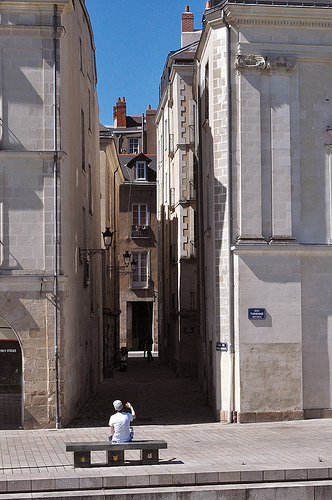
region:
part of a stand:
[150, 451, 159, 455]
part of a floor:
[229, 425, 260, 467]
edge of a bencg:
[127, 441, 140, 454]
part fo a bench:
[147, 444, 164, 471]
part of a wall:
[251, 381, 273, 420]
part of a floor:
[247, 430, 264, 457]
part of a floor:
[142, 397, 153, 407]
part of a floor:
[246, 416, 257, 433]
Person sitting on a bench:
[103, 395, 137, 468]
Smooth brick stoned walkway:
[0, 415, 331, 494]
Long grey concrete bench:
[61, 439, 173, 469]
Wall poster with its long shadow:
[245, 306, 274, 331]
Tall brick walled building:
[152, 0, 330, 428]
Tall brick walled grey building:
[0, 0, 110, 432]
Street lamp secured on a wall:
[77, 224, 116, 289]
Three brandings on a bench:
[78, 452, 156, 464]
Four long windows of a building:
[125, 126, 153, 294]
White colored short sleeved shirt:
[108, 410, 134, 445]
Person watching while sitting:
[108, 391, 143, 458]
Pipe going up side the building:
[47, 77, 65, 430]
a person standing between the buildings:
[139, 331, 158, 371]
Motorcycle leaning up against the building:
[119, 343, 130, 378]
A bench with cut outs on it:
[62, 438, 164, 466]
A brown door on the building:
[3, 331, 33, 442]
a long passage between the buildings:
[64, 331, 210, 425]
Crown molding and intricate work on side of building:
[234, 18, 326, 79]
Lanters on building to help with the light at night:
[74, 230, 119, 292]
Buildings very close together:
[99, 114, 212, 278]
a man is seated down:
[63, 381, 156, 460]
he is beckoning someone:
[103, 381, 151, 462]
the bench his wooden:
[40, 392, 173, 465]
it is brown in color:
[34, 431, 168, 467]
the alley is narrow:
[79, 322, 216, 407]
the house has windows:
[105, 125, 155, 297]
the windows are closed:
[117, 183, 154, 293]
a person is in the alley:
[129, 326, 162, 362]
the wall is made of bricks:
[203, 85, 319, 274]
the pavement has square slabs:
[189, 415, 271, 464]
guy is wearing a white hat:
[111, 396, 125, 414]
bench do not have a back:
[60, 439, 163, 465]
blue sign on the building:
[243, 302, 274, 323]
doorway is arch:
[2, 316, 39, 440]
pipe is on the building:
[48, 277, 66, 430]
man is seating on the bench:
[105, 399, 142, 449]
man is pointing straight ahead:
[122, 395, 140, 424]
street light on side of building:
[86, 218, 115, 259]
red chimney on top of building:
[112, 93, 133, 127]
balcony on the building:
[129, 249, 153, 294]